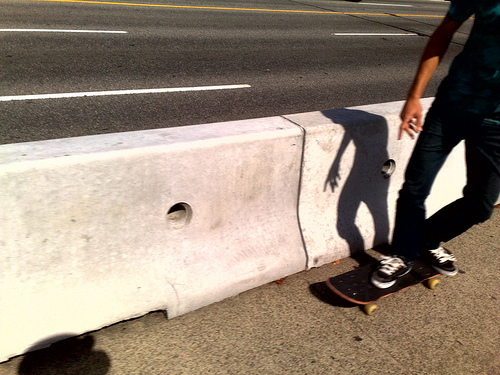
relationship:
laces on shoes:
[383, 257, 395, 275] [335, 216, 435, 325]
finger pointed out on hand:
[393, 123, 404, 141] [388, 95, 433, 145]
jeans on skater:
[389, 91, 499, 258] [373, 1, 498, 287]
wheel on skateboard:
[363, 300, 379, 317] [323, 245, 448, 320]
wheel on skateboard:
[427, 276, 442, 291] [323, 245, 448, 320]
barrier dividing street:
[12, 76, 491, 353] [0, 0, 474, 146]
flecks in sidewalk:
[325, 333, 391, 362] [213, 287, 444, 374]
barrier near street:
[0, 76, 491, 365] [7, 2, 499, 158]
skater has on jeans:
[373, 1, 498, 287] [389, 91, 499, 258]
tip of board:
[360, 284, 375, 306] [321, 251, 466, 303]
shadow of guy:
[322, 106, 394, 254] [371, 0, 498, 292]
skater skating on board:
[367, 1, 497, 290] [321, 251, 460, 316]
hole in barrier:
[167, 202, 192, 228] [0, 76, 491, 365]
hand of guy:
[395, 99, 422, 141] [371, 0, 498, 292]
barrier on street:
[0, 76, 491, 365] [0, 0, 474, 146]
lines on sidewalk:
[1, 0, 484, 149] [180, 314, 500, 375]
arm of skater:
[359, 30, 499, 205] [365, 0, 485, 291]